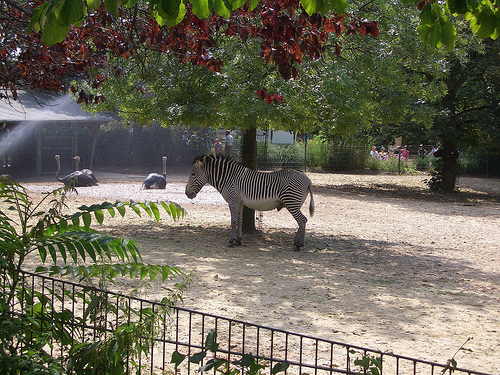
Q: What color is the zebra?
A: Black and white.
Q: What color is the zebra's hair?
A: Black.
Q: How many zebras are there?
A: 1.